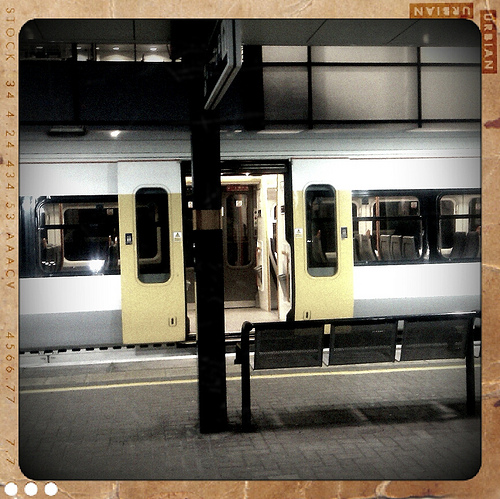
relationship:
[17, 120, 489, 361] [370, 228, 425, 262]
car has seat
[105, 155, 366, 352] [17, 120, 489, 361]
door of train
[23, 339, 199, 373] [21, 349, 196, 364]
spacer on beam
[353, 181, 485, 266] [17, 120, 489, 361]
window of passenger train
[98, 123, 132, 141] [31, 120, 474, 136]
light on ceiling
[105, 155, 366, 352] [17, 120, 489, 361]
door of subway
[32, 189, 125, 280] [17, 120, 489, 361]
window on side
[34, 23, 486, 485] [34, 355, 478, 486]
terminal has tile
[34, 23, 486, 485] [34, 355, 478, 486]
terminal has tiles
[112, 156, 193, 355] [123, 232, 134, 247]
door has handle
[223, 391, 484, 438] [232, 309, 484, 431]
shadow of bench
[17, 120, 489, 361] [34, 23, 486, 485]
train stop at station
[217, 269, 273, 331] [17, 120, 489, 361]
floor of train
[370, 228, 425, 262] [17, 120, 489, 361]
chairs inside train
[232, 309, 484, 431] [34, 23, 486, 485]
bench at station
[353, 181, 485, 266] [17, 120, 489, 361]
windows of train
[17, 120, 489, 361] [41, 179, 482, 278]
train without passengers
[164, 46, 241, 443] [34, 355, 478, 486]
column on platform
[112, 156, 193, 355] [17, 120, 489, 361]
door of train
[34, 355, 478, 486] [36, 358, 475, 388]
platform has a line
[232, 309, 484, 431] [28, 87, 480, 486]
bench in station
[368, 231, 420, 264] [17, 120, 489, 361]
seat in train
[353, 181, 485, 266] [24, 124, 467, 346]
window on side of subway